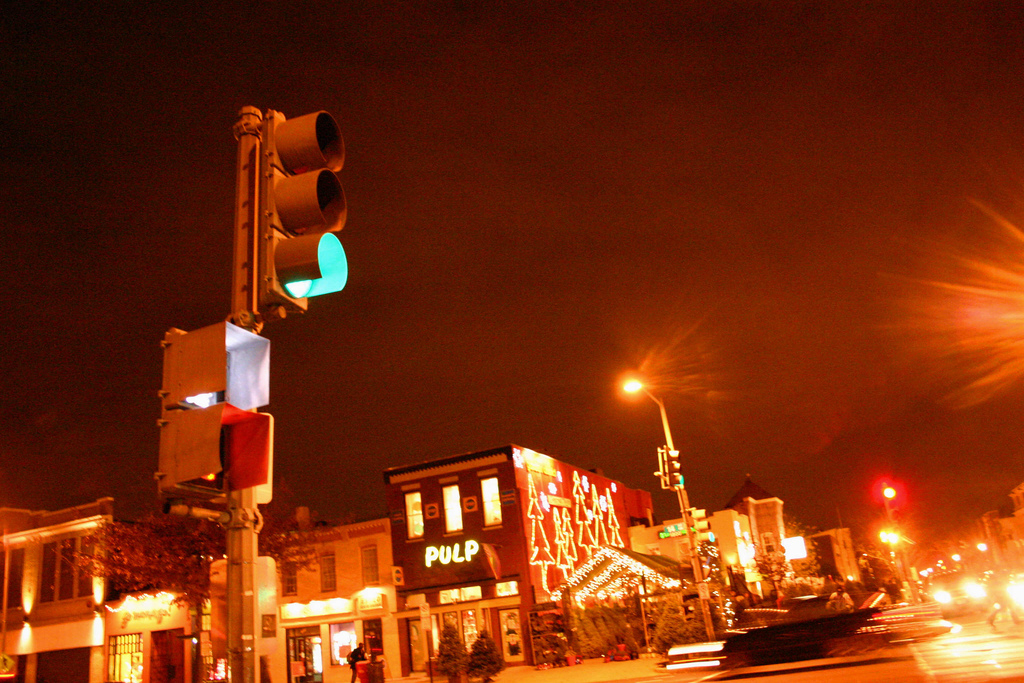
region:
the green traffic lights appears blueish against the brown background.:
[274, 231, 348, 304]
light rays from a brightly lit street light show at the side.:
[884, 181, 1022, 410]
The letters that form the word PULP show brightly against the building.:
[420, 538, 482, 565]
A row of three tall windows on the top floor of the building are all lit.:
[400, 473, 508, 540]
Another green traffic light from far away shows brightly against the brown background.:
[673, 470, 683, 487]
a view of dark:
[458, 50, 592, 161]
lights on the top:
[569, 309, 696, 453]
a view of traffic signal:
[214, 88, 369, 284]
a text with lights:
[319, 430, 515, 608]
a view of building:
[211, 439, 708, 678]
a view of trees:
[441, 603, 511, 677]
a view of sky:
[503, 72, 685, 212]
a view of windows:
[378, 414, 603, 627]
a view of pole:
[641, 443, 785, 639]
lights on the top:
[227, 53, 346, 275]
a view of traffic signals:
[129, 296, 300, 588]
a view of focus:
[906, 225, 996, 385]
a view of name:
[369, 495, 566, 606]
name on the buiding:
[351, 458, 573, 635]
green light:
[257, 218, 362, 311]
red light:
[872, 461, 923, 507]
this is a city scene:
[64, 81, 820, 661]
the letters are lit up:
[414, 504, 567, 599]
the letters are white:
[383, 496, 548, 591]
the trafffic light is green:
[142, 115, 570, 577]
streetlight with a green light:
[155, 86, 364, 674]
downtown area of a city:
[2, 437, 704, 679]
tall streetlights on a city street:
[610, 356, 737, 647]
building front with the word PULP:
[382, 440, 538, 678]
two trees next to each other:
[426, 613, 500, 680]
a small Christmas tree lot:
[560, 538, 725, 665]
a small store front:
[268, 514, 399, 680]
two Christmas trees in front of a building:
[383, 443, 532, 679]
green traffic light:
[239, 91, 350, 338]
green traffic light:
[656, 439, 688, 503]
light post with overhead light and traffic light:
[609, 352, 755, 679]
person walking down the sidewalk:
[347, 630, 376, 679]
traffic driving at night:
[916, 565, 1021, 635]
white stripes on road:
[906, 629, 1005, 675]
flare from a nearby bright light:
[888, 177, 1021, 437]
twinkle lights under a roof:
[561, 548, 679, 610]